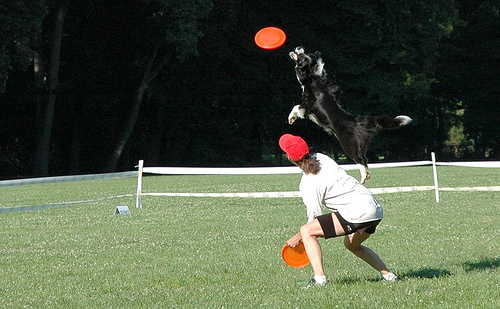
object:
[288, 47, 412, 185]
dog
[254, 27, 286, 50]
frisbee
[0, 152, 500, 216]
fence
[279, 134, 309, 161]
cap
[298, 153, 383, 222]
thsirt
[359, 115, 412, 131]
tail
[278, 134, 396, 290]
woman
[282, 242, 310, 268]
frisbee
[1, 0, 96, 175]
trees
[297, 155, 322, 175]
hair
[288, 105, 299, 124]
paw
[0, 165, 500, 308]
ground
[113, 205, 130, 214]
paper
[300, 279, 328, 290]
shoes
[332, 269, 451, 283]
shadow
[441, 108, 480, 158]
path